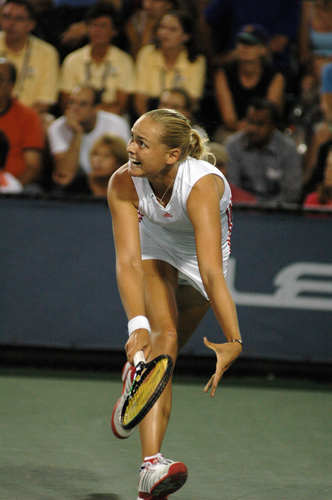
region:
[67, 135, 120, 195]
spectator sitting in stands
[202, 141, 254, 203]
spectator sitting in stands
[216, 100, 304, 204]
spectator sitting in stands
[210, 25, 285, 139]
spectator sitting in stands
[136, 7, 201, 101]
spectator sitting in stands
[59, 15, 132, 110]
spectator sitting in stands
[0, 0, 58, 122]
spectator sitting in stands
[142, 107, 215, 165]
the hair is blond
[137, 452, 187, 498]
the shoe is red and white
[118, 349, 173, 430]
the yellow and black tennis racquet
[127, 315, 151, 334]
the white wristband on the woman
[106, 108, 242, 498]
the woman is playing tennis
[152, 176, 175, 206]
the necklace on the woman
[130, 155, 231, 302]
the white clothes on the woman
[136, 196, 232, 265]
the red on the woman's clothes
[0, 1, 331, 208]
the blurred people in the audience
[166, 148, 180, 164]
the ear on the woman's head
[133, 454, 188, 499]
a woman's red and white tennis shoe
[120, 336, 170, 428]
a black and yellow racket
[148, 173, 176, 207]
a woman's necklace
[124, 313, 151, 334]
a white wristband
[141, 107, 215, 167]
a woman's blonde hair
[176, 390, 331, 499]
part of a tennis court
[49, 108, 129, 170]
part of a man's white shirt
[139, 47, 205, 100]
a woman's yellow shirt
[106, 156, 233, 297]
a woman's red and white outfit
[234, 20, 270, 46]
a blue baseball cap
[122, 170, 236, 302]
the dress is white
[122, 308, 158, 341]
the wristband is white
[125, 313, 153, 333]
the wristband is white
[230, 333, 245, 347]
watch on woman's wrist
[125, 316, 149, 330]
white band on woman's wrist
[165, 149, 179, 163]
an ear on the woman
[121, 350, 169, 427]
tennis racket in player's hand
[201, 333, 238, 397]
fingers on woman's hand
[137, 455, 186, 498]
athletic shoe on woman's foot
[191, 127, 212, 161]
blond pony tail on woman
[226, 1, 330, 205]
spectators in the audience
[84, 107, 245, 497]
woman playing tennis on court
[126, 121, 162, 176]
face on the woman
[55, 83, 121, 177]
a fan sitting in stand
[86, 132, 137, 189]
a fan sitting in stand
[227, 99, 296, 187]
a fan sitting in stand